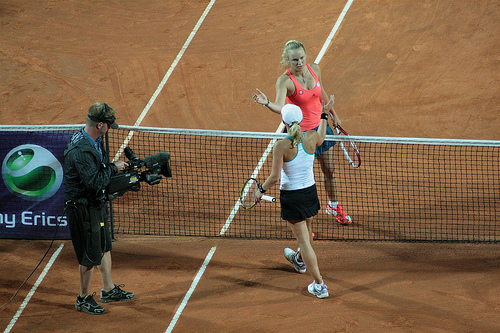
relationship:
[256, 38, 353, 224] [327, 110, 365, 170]
woman holds tennis racquet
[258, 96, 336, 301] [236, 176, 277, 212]
woman holds tennis racquet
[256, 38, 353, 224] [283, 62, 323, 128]
woman wears tank top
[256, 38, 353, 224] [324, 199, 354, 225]
woman wearing shoes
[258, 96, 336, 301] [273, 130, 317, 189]
woman wears tank top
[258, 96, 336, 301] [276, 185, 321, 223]
woman wears black skirt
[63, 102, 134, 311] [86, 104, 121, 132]
man wears visor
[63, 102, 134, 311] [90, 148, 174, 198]
man holds camera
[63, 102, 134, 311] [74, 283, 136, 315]
man wearing tennis shoes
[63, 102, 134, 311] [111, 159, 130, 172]
man has hand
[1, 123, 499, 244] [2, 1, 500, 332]
net in ground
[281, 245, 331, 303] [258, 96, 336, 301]
two shoes on woman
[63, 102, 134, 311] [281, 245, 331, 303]
man has tennis shoes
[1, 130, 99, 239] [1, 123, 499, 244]
display on net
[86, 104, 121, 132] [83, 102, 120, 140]
visor on head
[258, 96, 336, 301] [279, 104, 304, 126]
woman wearing ball cap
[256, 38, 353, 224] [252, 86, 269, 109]
woman has hand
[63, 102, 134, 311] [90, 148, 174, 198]
man holding camera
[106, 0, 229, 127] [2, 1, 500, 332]
line on ground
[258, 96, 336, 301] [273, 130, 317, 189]
woman wearing white shirt